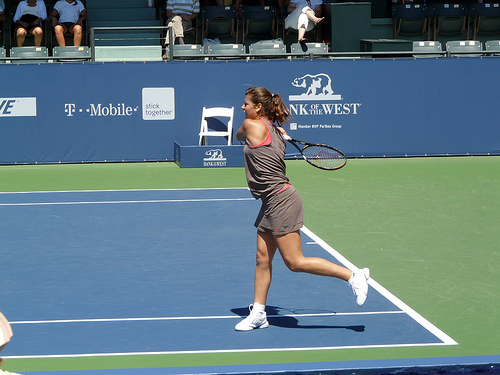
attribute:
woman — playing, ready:
[235, 87, 373, 334]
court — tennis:
[5, 165, 406, 357]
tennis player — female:
[234, 83, 374, 332]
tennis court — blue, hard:
[0, 158, 500, 368]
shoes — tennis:
[233, 265, 373, 332]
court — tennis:
[363, 156, 499, 326]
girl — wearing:
[234, 173, 375, 338]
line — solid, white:
[2, 310, 403, 325]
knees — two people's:
[259, 239, 306, 286]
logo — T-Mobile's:
[61, 99, 135, 120]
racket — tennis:
[277, 127, 349, 171]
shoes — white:
[231, 259, 391, 339]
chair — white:
[196, 104, 237, 150]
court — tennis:
[0, 156, 497, 374]